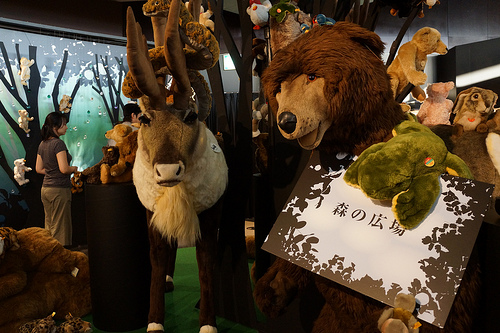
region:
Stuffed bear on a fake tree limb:
[385, 25, 450, 111]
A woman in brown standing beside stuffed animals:
[33, 108, 80, 254]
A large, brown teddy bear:
[253, 14, 393, 160]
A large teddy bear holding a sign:
[253, 22, 489, 331]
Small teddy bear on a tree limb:
[16, 103, 35, 135]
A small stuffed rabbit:
[450, 82, 497, 133]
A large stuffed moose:
[123, 0, 227, 330]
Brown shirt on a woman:
[36, 134, 73, 189]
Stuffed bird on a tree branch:
[244, 0, 271, 33]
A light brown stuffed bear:
[391, 27, 449, 106]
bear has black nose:
[277, 111, 298, 136]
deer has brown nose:
[148, 163, 185, 183]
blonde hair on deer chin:
[158, 194, 193, 239]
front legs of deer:
[139, 288, 222, 331]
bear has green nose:
[365, 149, 410, 192]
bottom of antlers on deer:
[125, 32, 192, 97]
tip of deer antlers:
[116, 1, 186, 18]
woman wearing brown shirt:
[46, 146, 54, 163]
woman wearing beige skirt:
[50, 194, 62, 214]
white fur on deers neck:
[201, 159, 225, 191]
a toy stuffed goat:
[123, 0, 230, 332]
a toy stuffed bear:
[253, 23, 480, 332]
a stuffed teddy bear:
[388, 26, 447, 96]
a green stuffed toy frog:
[343, 118, 473, 231]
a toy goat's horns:
[128, 5, 160, 107]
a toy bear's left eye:
[305, 73, 320, 83]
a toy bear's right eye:
[273, 81, 283, 94]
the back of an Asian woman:
[35, 112, 77, 245]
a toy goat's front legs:
[145, 218, 217, 332]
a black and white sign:
[262, 145, 494, 330]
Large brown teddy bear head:
[248, 25, 402, 154]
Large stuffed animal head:
[120, 10, 228, 235]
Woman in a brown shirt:
[31, 111, 73, 239]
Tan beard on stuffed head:
[155, 180, 199, 243]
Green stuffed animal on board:
[340, 120, 455, 224]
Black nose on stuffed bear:
[278, 111, 297, 130]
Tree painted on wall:
[3, 42, 81, 204]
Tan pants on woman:
[40, 183, 75, 245]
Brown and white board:
[260, 148, 495, 328]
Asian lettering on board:
[330, 193, 408, 247]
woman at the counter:
[23, 95, 79, 242]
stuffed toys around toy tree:
[118, 3, 486, 325]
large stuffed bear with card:
[261, 18, 460, 323]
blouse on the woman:
[38, 134, 71, 184]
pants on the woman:
[33, 181, 72, 243]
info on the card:
[323, 198, 412, 240]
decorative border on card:
[428, 180, 468, 327]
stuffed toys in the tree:
[131, 4, 283, 113]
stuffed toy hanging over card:
[346, 114, 475, 235]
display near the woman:
[6, 44, 121, 177]